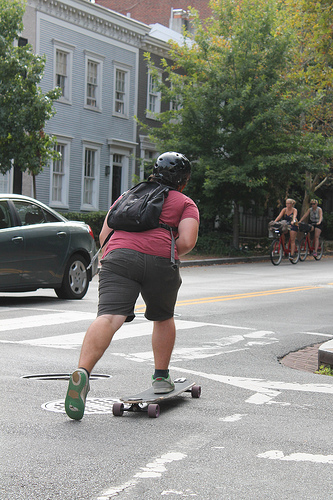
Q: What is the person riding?
A: A skateboard.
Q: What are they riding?
A: Bikes.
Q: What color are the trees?
A: Green.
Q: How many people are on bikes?
A: Two.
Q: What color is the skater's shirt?
A: Red.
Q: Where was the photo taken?
A: On the street.